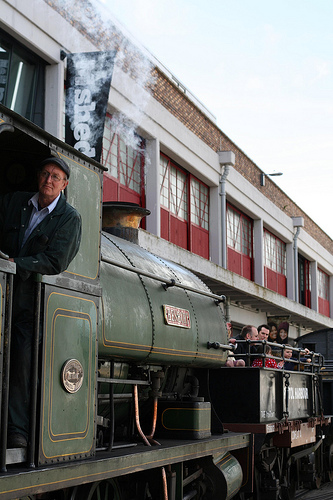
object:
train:
[2, 264, 333, 499]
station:
[62, 22, 312, 257]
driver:
[6, 154, 82, 413]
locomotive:
[0, 121, 217, 499]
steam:
[120, 71, 137, 98]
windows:
[190, 174, 206, 227]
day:
[220, 17, 319, 140]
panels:
[170, 211, 190, 249]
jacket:
[6, 204, 77, 259]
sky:
[219, 10, 321, 111]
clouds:
[195, 37, 282, 79]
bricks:
[184, 113, 190, 123]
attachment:
[57, 355, 95, 399]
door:
[47, 289, 100, 466]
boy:
[298, 347, 313, 368]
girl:
[256, 346, 274, 370]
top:
[259, 358, 273, 369]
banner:
[265, 316, 290, 343]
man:
[240, 326, 263, 347]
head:
[259, 328, 267, 343]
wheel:
[303, 442, 330, 496]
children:
[283, 345, 293, 362]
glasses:
[30, 166, 73, 190]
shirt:
[12, 198, 69, 255]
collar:
[26, 197, 53, 212]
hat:
[40, 153, 76, 174]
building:
[140, 98, 332, 302]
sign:
[47, 39, 120, 157]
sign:
[281, 380, 319, 409]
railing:
[250, 342, 317, 368]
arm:
[4, 250, 83, 275]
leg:
[10, 292, 38, 432]